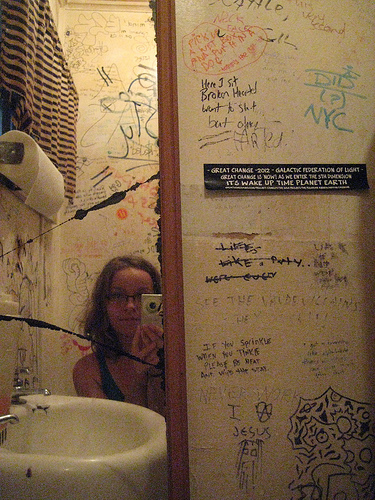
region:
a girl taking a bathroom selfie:
[77, 251, 177, 405]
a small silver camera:
[137, 294, 165, 342]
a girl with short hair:
[82, 257, 158, 366]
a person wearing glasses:
[97, 283, 153, 310]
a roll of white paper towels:
[1, 126, 68, 226]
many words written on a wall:
[176, 1, 373, 493]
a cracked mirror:
[0, 1, 173, 490]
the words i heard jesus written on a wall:
[221, 398, 277, 445]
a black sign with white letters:
[205, 159, 371, 195]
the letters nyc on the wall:
[304, 99, 354, 133]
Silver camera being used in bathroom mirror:
[140, 294, 163, 335]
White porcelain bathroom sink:
[0, 362, 172, 498]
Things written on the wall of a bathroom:
[178, 0, 374, 495]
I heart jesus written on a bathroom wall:
[227, 399, 279, 449]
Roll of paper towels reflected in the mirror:
[1, 129, 72, 220]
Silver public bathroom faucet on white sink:
[11, 365, 55, 402]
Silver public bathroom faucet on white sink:
[0, 411, 19, 428]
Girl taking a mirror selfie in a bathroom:
[71, 251, 170, 415]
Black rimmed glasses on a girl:
[104, 287, 151, 312]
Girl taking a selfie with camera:
[71, 254, 175, 413]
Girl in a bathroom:
[71, 253, 165, 424]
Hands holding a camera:
[127, 292, 166, 375]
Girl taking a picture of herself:
[70, 254, 170, 420]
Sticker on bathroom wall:
[200, 160, 371, 194]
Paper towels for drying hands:
[0, 125, 68, 221]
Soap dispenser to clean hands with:
[0, 289, 21, 434]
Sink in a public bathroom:
[0, 360, 170, 498]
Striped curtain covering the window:
[1, 0, 80, 205]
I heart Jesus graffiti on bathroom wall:
[223, 398, 276, 491]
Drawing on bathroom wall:
[284, 388, 374, 498]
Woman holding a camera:
[77, 250, 164, 371]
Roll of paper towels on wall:
[0, 126, 67, 224]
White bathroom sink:
[1, 387, 167, 496]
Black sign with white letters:
[199, 159, 369, 197]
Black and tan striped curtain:
[0, 0, 79, 203]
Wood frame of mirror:
[154, 71, 192, 497]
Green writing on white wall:
[302, 58, 368, 139]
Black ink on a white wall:
[203, 237, 311, 290]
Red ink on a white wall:
[180, 10, 268, 75]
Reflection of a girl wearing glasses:
[71, 252, 158, 363]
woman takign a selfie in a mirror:
[75, 259, 170, 405]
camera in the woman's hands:
[142, 292, 165, 339]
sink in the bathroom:
[0, 384, 171, 498]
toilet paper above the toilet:
[4, 129, 66, 227]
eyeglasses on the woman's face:
[103, 288, 142, 307]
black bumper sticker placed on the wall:
[201, 162, 370, 192]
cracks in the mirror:
[0, 170, 166, 370]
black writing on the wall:
[222, 394, 280, 498]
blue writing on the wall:
[301, 60, 367, 136]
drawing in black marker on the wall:
[286, 387, 374, 498]